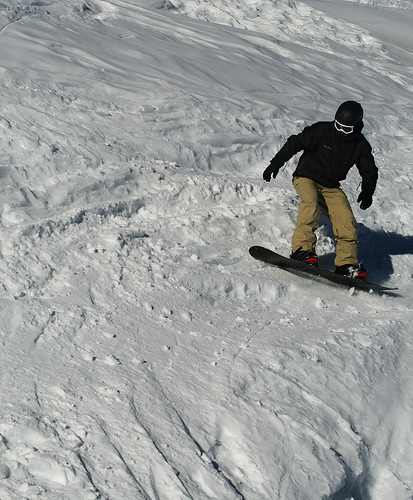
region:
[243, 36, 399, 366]
man is on snowboard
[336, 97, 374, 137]
man wears black hat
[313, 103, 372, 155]
man is wearing goggles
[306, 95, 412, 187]
man wears black coat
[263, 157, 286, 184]
man wears black gloves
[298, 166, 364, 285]
man wears tan pants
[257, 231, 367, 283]
man wears black shoes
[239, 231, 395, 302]
man has black snowboard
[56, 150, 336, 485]
deep tracks in snow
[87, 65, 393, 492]
man snowboards down hill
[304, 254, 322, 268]
red bottom of skiiers right shoe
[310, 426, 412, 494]
shadow on right bottom photo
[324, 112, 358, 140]
white goggles with black lenses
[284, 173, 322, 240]
right leg of tan ski pants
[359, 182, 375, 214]
skiers left ski glove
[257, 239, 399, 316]
balck snowboard on top of snow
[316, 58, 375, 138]
black helmet on top of skiers head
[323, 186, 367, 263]
skiers left leg with tan snowpants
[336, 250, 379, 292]
black snow boots with red bottoms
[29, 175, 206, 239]
tracks in snow on left of picture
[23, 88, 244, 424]
a snow white covered ground.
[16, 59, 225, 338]
a huge field of snow.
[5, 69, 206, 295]
the snow is beautiful and white.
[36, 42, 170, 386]
the snow is cold and deep.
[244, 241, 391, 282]
a black snow board.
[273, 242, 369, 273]
a man is wearing black and orange sneakers.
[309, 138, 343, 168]
a man is wearing a black jacket.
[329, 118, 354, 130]
a man is wearing white goggles.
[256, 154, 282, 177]
a man is wearing black gloves.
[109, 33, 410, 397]
a man is snow boarding in the snow.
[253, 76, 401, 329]
the person on the snowboard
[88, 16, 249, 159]
the snow covered slope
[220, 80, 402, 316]
the person is snowboarding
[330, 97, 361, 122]
the helmet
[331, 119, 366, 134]
the goggles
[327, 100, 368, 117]
the helmet is black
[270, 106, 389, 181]
the person wearing a jacket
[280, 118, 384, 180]
the jacket is black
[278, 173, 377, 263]
the person wearing the tan ski pants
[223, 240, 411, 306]
the snowboard is black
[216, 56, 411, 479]
Man who is skiing.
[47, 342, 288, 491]
Tracks in the snow.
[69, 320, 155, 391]
Balls of snow on the snow.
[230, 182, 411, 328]
Snowboard under the guy.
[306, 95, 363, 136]
Snow goggles on the man.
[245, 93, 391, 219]
Black jacket on the man.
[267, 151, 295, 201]
Gloves on the man.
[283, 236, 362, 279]
Red on the man's boots.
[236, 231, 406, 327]
Snow under the board.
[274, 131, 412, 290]
Khaki pants on the man.